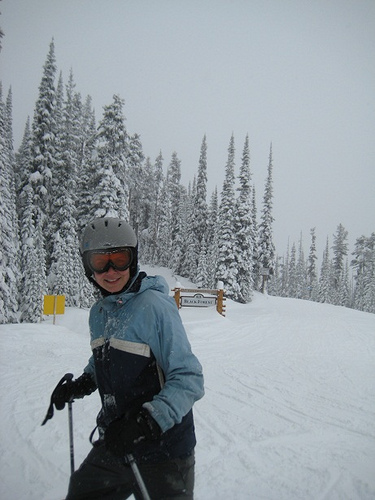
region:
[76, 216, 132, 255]
a grey helmet on top of a person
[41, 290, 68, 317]
a yellow sign above the snow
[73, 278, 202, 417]
a light blue winter jacket on a person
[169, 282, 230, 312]
a big white sign on top of the snow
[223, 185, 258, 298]
a snow covered pine tree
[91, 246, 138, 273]
orange goggles on the face of a person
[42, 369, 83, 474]
a ski pole held in a hand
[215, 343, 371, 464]
ski tracks in the snow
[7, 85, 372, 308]
a forest of snow covered pine trees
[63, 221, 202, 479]
a very happy skier on top of snow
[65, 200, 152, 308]
head of a person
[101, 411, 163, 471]
hand of a person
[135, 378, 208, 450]
arm of a person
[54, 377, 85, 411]
hand of a person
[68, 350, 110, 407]
arm of a person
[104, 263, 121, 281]
nose of a person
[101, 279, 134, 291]
smile of a person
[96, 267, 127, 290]
mouth of a person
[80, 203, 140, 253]
helmet of a person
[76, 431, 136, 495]
leg of a person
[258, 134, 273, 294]
Snow on the tree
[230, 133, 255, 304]
Snow on the tree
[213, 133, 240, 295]
Snow on the tree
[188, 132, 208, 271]
Snow on the tree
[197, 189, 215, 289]
Snow on the tree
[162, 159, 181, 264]
Snow on the tree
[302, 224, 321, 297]
Snow on the tree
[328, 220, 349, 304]
Snow on the tree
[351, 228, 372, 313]
Snow on the tree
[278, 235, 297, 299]
Snow on the tree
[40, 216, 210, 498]
female skier dressed in blue and black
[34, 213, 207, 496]
female skier with blue and black jacket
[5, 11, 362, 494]
skier on the slope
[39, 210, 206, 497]
skier in helmet with ski poles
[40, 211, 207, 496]
skier in sunglasses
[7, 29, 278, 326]
snow covered pine trees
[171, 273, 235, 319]
sign on the ski slope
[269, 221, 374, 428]
ski slope with snow and trees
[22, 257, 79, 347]
yellow sign in the snow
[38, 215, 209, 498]
female skier with blue, white and black jacket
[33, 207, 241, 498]
Person is in the foreground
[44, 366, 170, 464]
Person is wearing black gloves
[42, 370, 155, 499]
Person is holding silver ski poles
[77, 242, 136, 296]
Person is looking at the camera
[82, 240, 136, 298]
Person is wearing goggles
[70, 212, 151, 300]
Person is wearing a helmet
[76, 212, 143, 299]
The helmet is gray in color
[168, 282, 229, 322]
A sign in the background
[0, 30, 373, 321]
Snow is covering the trees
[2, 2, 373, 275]
The sky is gray in color